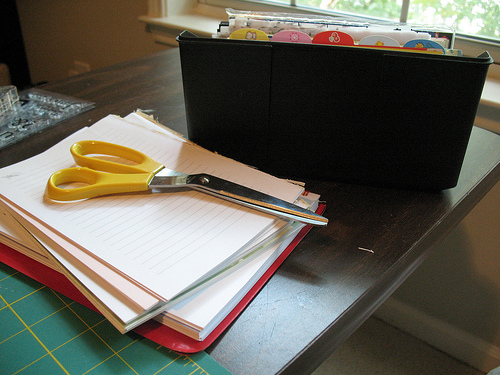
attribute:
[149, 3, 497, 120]
window — white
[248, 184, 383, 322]
table — crafting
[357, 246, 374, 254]
white line — small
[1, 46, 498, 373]
table — brown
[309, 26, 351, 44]
tab — colored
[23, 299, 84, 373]
mat — cutting, plastic, green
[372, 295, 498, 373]
trim — white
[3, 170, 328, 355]
book — red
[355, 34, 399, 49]
tab — colored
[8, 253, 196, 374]
graph — green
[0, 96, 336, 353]
tab — colored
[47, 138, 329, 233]
scissors — yellow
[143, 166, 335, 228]
scissor blades — scissors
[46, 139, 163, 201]
handle — yellow, orange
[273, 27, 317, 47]
tab — colored